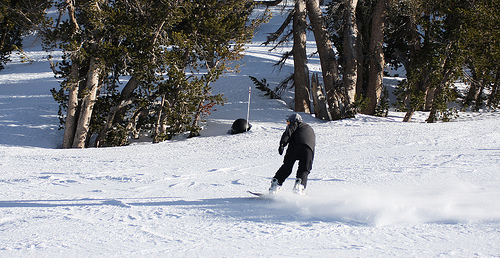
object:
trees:
[294, 0, 309, 111]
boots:
[291, 179, 305, 195]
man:
[271, 114, 316, 191]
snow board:
[246, 190, 262, 196]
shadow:
[0, 198, 272, 217]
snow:
[0, 0, 498, 258]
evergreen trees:
[46, 9, 123, 148]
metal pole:
[246, 86, 252, 131]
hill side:
[2, 31, 497, 253]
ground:
[0, 0, 496, 255]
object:
[226, 118, 251, 134]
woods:
[61, 67, 79, 149]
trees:
[132, 0, 250, 143]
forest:
[0, 0, 495, 148]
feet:
[269, 188, 279, 194]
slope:
[0, 111, 499, 258]